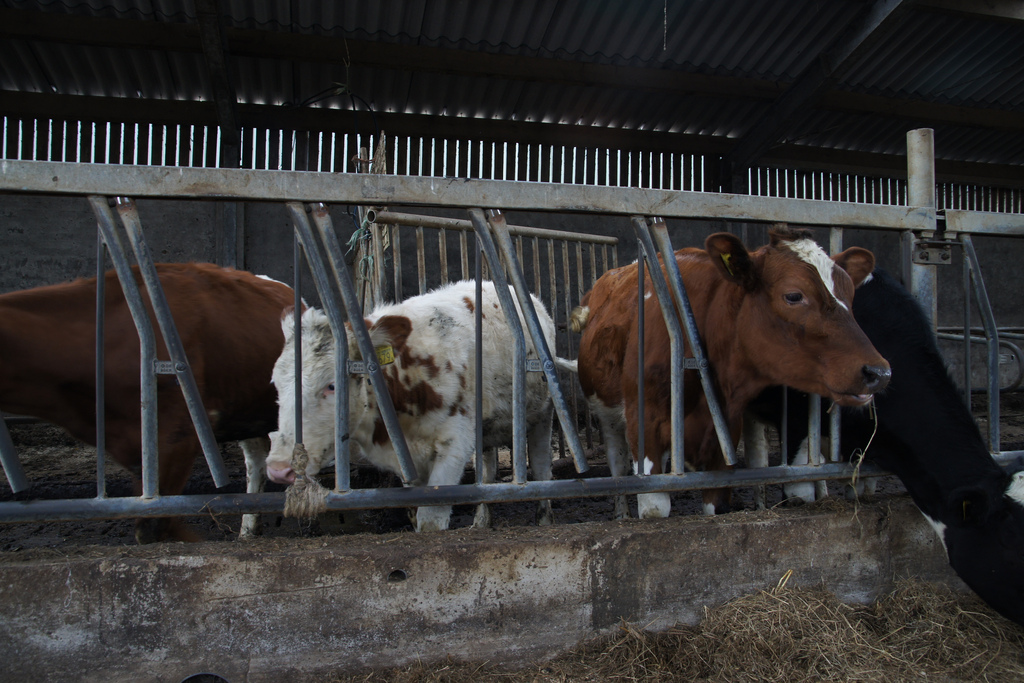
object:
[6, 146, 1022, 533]
fence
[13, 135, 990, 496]
fence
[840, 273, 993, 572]
cow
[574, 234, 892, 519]
cow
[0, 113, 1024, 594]
cage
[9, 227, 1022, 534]
cows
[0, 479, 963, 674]
barrier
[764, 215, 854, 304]
spot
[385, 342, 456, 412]
spot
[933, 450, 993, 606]
head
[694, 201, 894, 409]
head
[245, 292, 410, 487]
head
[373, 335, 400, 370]
tag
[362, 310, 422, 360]
ear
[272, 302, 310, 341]
ear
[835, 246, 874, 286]
ear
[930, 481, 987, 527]
ear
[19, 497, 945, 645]
wall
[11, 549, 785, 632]
surface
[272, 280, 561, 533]
cow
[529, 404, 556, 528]
leg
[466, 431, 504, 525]
leg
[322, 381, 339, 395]
eye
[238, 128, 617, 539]
middle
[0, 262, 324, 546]
cow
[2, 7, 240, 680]
left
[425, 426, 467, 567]
leg